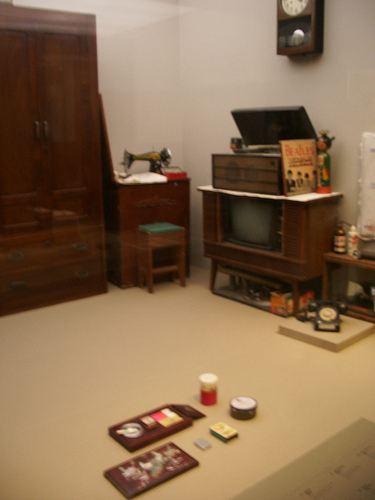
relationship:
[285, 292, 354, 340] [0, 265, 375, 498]
phone on floor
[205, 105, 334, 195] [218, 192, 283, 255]
record player on top of television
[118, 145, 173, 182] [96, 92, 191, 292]
sewing machine on dresser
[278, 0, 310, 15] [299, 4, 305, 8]
black number on clock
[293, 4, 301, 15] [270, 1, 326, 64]
number on clock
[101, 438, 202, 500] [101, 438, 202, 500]
item on item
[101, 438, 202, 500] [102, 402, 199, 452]
item on tray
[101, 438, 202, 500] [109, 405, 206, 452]
item on wooden tray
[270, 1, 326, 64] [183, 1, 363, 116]
clock on wall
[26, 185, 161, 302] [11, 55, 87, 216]
reflection on window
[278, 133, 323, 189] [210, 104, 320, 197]
record on record player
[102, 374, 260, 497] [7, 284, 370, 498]
objects on floor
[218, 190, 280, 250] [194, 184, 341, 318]
television inside of stand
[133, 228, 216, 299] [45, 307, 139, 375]
stool on floor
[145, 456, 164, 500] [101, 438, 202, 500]
item on item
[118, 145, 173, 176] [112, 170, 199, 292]
sewing machine on stand